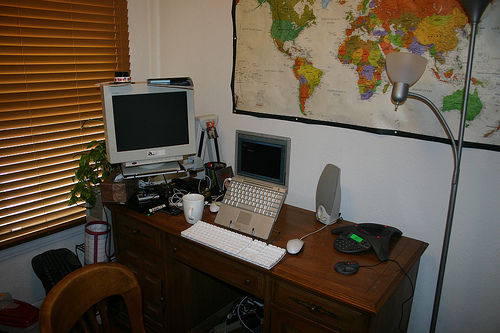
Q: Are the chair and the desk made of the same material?
A: Yes, both the chair and the desk are made of wood.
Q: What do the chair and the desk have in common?
A: The material, both the chair and the desk are wooden.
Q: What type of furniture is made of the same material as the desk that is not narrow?
A: The chair is made of the same material as the desk.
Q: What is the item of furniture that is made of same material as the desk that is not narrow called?
A: The piece of furniture is a chair.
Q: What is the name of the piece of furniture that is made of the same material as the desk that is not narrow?
A: The piece of furniture is a chair.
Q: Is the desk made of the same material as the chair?
A: Yes, both the desk and the chair are made of wood.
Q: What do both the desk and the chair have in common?
A: The material, both the desk and the chair are wooden.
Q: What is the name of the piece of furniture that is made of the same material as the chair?
A: The piece of furniture is a desk.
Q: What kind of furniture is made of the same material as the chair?
A: The desk is made of the same material as the chair.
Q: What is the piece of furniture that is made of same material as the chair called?
A: The piece of furniture is a desk.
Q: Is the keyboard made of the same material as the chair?
A: No, the keyboard is made of plastic and the chair is made of wood.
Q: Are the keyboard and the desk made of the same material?
A: No, the keyboard is made of plastic and the desk is made of wood.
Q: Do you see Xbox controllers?
A: No, there are no Xbox controllers.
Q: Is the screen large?
A: Yes, the screen is large.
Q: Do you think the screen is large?
A: Yes, the screen is large.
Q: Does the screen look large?
A: Yes, the screen is large.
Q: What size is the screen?
A: The screen is large.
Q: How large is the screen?
A: The screen is large.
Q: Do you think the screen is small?
A: No, the screen is large.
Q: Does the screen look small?
A: No, the screen is large.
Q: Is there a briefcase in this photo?
A: No, there are no briefcases.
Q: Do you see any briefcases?
A: No, there are no briefcases.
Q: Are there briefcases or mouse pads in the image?
A: No, there are no briefcases or mouse pads.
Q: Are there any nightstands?
A: No, there are no nightstands.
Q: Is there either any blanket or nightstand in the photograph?
A: No, there are no nightstands or blankets.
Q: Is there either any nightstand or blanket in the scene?
A: No, there are no nightstands or blankets.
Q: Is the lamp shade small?
A: Yes, the lamp shade is small.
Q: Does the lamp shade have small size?
A: Yes, the lamp shade is small.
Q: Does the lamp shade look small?
A: Yes, the lamp shade is small.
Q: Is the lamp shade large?
A: No, the lamp shade is small.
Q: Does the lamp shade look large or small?
A: The lamp shade is small.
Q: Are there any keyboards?
A: Yes, there is a keyboard.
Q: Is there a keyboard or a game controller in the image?
A: Yes, there is a keyboard.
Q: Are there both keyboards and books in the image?
A: No, there is a keyboard but no books.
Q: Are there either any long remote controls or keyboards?
A: Yes, there is a long keyboard.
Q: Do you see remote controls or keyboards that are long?
A: Yes, the keyboard is long.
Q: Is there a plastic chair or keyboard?
A: Yes, there is a plastic keyboard.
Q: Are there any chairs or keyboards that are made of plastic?
A: Yes, the keyboard is made of plastic.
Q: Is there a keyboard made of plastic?
A: Yes, there is a keyboard that is made of plastic.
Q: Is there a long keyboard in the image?
A: Yes, there is a long keyboard.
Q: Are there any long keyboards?
A: Yes, there is a long keyboard.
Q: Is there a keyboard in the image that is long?
A: Yes, there is a keyboard that is long.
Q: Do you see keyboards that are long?
A: Yes, there is a keyboard that is long.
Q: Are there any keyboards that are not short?
A: Yes, there is a long keyboard.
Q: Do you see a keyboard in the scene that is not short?
A: Yes, there is a long keyboard.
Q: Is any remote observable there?
A: No, there are no remote controls.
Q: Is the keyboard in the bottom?
A: Yes, the keyboard is in the bottom of the image.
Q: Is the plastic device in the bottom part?
A: Yes, the keyboard is in the bottom of the image.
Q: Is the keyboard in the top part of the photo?
A: No, the keyboard is in the bottom of the image.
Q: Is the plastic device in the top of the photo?
A: No, the keyboard is in the bottom of the image.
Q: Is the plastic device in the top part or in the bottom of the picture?
A: The keyboard is in the bottom of the image.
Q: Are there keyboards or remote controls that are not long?
A: No, there is a keyboard but it is long.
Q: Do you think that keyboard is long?
A: Yes, the keyboard is long.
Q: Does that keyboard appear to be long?
A: Yes, the keyboard is long.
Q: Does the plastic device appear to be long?
A: Yes, the keyboard is long.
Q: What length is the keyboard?
A: The keyboard is long.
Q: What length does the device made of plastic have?
A: The keyboard has long length.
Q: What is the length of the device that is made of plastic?
A: The keyboard is long.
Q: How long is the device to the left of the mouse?
A: The keyboard is long.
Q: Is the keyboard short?
A: No, the keyboard is long.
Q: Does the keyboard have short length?
A: No, the keyboard is long.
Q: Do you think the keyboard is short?
A: No, the keyboard is long.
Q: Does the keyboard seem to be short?
A: No, the keyboard is long.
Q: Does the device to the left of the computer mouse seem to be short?
A: No, the keyboard is long.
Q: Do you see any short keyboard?
A: No, there is a keyboard but it is long.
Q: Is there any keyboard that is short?
A: No, there is a keyboard but it is long.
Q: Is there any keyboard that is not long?
A: No, there is a keyboard but it is long.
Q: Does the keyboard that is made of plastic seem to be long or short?
A: The keyboard is long.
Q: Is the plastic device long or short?
A: The keyboard is long.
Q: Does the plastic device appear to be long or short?
A: The keyboard is long.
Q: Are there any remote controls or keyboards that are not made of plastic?
A: No, there is a keyboard but it is made of plastic.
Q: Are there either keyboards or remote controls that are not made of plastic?
A: No, there is a keyboard but it is made of plastic.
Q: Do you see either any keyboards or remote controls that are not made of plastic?
A: No, there is a keyboard but it is made of plastic.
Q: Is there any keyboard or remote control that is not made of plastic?
A: No, there is a keyboard but it is made of plastic.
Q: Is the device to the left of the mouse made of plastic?
A: Yes, the keyboard is made of plastic.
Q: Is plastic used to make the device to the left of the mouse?
A: Yes, the keyboard is made of plastic.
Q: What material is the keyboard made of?
A: The keyboard is made of plastic.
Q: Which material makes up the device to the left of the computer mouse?
A: The keyboard is made of plastic.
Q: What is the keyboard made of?
A: The keyboard is made of plastic.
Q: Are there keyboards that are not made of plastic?
A: No, there is a keyboard but it is made of plastic.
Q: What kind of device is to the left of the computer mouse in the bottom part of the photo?
A: The device is a keyboard.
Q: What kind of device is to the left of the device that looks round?
A: The device is a keyboard.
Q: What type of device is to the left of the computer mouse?
A: The device is a keyboard.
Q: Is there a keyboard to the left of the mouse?
A: Yes, there is a keyboard to the left of the mouse.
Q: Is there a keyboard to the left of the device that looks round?
A: Yes, there is a keyboard to the left of the mouse.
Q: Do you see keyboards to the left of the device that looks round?
A: Yes, there is a keyboard to the left of the mouse.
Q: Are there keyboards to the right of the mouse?
A: No, the keyboard is to the left of the mouse.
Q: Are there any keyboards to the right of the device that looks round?
A: No, the keyboard is to the left of the mouse.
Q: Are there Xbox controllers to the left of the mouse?
A: No, there is a keyboard to the left of the mouse.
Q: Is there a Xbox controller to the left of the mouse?
A: No, there is a keyboard to the left of the mouse.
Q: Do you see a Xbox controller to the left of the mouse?
A: No, there is a keyboard to the left of the mouse.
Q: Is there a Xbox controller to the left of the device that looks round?
A: No, there is a keyboard to the left of the mouse.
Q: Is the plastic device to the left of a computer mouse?
A: Yes, the keyboard is to the left of a computer mouse.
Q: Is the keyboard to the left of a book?
A: No, the keyboard is to the left of a computer mouse.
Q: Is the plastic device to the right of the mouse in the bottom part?
A: No, the keyboard is to the left of the computer mouse.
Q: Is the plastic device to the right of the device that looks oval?
A: No, the keyboard is to the left of the computer mouse.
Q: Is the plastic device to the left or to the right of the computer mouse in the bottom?
A: The keyboard is to the left of the mouse.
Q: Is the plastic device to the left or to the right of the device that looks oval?
A: The keyboard is to the left of the mouse.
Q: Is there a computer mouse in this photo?
A: Yes, there is a computer mouse.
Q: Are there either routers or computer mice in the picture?
A: Yes, there is a computer mouse.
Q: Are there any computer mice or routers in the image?
A: Yes, there is a computer mouse.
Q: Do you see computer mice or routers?
A: Yes, there is a computer mouse.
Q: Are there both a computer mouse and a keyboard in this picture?
A: Yes, there are both a computer mouse and a keyboard.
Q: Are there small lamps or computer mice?
A: Yes, there is a small computer mouse.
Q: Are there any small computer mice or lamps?
A: Yes, there is a small computer mouse.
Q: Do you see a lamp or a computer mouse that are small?
A: Yes, the computer mouse is small.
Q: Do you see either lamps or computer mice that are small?
A: Yes, the computer mouse is small.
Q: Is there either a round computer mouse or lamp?
A: Yes, there is a round computer mouse.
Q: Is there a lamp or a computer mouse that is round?
A: Yes, the computer mouse is round.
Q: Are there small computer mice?
A: Yes, there is a small computer mouse.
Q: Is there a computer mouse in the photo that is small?
A: Yes, there is a computer mouse that is small.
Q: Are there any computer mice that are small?
A: Yes, there is a computer mouse that is small.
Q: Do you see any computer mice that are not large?
A: Yes, there is a small computer mouse.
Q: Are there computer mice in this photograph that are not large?
A: Yes, there is a small computer mouse.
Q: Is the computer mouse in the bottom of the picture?
A: Yes, the computer mouse is in the bottom of the image.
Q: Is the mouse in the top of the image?
A: No, the mouse is in the bottom of the image.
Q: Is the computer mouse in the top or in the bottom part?
A: The computer mouse is in the bottom of the image.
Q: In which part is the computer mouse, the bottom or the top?
A: The computer mouse is in the bottom of the image.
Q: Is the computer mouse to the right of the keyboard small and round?
A: Yes, the mouse is small and round.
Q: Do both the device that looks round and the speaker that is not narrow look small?
A: Yes, both the mouse and the speaker are small.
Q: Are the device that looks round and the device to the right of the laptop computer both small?
A: Yes, both the mouse and the speaker are small.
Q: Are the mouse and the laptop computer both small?
A: Yes, both the mouse and the laptop computer are small.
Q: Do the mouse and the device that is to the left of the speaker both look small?
A: Yes, both the mouse and the laptop computer are small.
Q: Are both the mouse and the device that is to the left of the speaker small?
A: Yes, both the mouse and the laptop computer are small.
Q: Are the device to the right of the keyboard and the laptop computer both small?
A: Yes, both the mouse and the laptop computer are small.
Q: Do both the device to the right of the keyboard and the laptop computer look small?
A: Yes, both the mouse and the laptop computer are small.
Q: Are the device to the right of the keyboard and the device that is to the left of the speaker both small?
A: Yes, both the mouse and the laptop computer are small.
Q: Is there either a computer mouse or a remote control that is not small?
A: No, there is a computer mouse but it is small.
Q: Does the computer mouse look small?
A: Yes, the computer mouse is small.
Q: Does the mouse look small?
A: Yes, the mouse is small.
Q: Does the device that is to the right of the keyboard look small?
A: Yes, the mouse is small.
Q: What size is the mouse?
A: The mouse is small.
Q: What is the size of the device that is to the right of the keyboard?
A: The mouse is small.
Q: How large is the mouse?
A: The mouse is small.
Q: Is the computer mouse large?
A: No, the computer mouse is small.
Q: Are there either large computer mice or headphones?
A: No, there is a computer mouse but it is small.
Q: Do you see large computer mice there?
A: No, there is a computer mouse but it is small.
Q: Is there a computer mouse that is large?
A: No, there is a computer mouse but it is small.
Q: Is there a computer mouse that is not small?
A: No, there is a computer mouse but it is small.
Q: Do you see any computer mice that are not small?
A: No, there is a computer mouse but it is small.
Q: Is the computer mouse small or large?
A: The computer mouse is small.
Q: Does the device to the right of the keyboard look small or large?
A: The computer mouse is small.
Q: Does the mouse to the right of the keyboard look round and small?
A: Yes, the computer mouse is round and small.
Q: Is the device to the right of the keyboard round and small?
A: Yes, the computer mouse is round and small.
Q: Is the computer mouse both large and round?
A: No, the computer mouse is round but small.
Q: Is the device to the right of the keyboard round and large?
A: No, the computer mouse is round but small.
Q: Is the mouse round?
A: Yes, the mouse is round.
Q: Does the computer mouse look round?
A: Yes, the computer mouse is round.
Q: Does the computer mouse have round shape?
A: Yes, the computer mouse is round.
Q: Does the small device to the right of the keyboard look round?
A: Yes, the computer mouse is round.